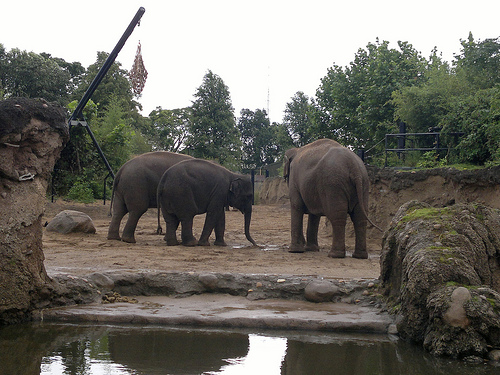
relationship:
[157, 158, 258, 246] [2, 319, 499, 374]
elephant near elephants water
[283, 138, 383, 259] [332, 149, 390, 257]
elephant has tail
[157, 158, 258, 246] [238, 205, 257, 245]
elephant has trunk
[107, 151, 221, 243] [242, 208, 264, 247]
elephant has trunk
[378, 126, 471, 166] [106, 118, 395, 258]
fence above elephants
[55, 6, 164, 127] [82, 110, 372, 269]
pole above elephants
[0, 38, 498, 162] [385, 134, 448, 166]
green tree behind fence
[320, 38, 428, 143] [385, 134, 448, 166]
green tree behind fence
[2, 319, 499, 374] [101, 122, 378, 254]
elephants water in front of elephants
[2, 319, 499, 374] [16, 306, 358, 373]
elephants water in water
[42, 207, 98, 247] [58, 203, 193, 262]
boulder on ground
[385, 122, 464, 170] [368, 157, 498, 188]
fence on ledge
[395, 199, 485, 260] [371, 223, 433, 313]
moss growing on dirt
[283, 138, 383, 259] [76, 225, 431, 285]
elephant in pen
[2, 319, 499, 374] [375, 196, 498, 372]
elephants water beside stone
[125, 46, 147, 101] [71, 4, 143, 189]
net hanging from winch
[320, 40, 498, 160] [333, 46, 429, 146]
trees with leaves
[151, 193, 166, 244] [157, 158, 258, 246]
tail of elephant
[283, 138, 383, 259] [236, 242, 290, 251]
elephant at watering hole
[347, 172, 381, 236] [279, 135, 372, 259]
tail of elephant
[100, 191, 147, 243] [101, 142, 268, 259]
legs of elephants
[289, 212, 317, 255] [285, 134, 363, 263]
legs of elephant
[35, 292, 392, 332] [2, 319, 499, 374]
step leading into elephants water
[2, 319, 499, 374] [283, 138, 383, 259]
elephants water of elephant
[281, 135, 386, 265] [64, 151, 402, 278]
elephant in area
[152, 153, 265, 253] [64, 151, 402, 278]
elephant in area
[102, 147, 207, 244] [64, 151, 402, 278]
elephant in area